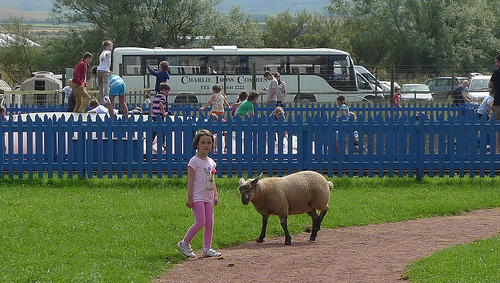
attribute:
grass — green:
[24, 186, 146, 281]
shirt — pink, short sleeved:
[186, 158, 220, 206]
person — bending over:
[92, 64, 132, 124]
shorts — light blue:
[106, 80, 128, 98]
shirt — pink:
[189, 158, 213, 199]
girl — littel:
[176, 106, 218, 254]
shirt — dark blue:
[146, 56, 171, 93]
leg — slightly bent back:
[176, 202, 203, 258]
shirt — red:
[70, 62, 90, 87]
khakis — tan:
[74, 80, 91, 112]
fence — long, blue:
[3, 110, 495, 175]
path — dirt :
[165, 202, 496, 281]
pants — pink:
[183, 201, 216, 246]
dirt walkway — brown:
[194, 211, 486, 278]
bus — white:
[104, 43, 391, 125]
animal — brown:
[237, 168, 337, 248]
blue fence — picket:
[0, 101, 497, 176]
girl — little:
[180, 132, 225, 255]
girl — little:
[173, 123, 225, 262]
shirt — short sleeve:
[183, 155, 219, 205]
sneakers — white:
[155, 236, 231, 266]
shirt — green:
[236, 96, 259, 126]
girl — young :
[173, 120, 232, 258]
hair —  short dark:
[189, 127, 216, 157]